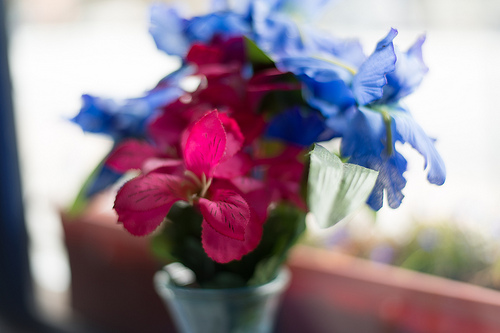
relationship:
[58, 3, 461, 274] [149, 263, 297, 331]
flowers in vase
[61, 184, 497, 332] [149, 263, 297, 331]
basket behind vase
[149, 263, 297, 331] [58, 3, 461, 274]
vase with flowers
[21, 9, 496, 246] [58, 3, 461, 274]
light behind flowers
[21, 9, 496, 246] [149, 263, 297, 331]
light behind vase